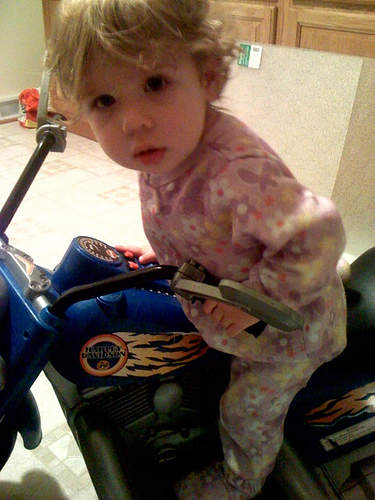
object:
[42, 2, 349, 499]
baby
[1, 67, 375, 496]
motorcycle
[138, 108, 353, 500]
jammies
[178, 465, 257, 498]
feet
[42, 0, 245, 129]
hair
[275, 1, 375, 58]
cabinet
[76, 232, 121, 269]
speedometer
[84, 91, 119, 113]
eyes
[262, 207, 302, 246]
flower print